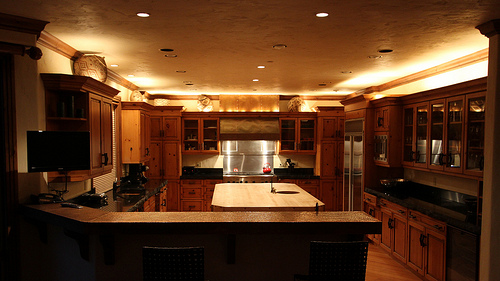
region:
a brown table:
[214, 180, 316, 208]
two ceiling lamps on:
[137, 11, 329, 19]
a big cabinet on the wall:
[50, 77, 119, 178]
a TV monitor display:
[26, 129, 91, 172]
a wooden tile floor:
[375, 252, 399, 279]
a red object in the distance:
[262, 166, 271, 174]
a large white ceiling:
[118, 9, 357, 71]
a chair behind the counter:
[147, 243, 203, 278]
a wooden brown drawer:
[406, 207, 445, 235]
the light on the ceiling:
[347, 70, 396, 94]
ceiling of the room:
[79, 0, 368, 101]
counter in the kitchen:
[68, 205, 377, 234]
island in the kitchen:
[215, 180, 320, 207]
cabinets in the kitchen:
[365, 195, 450, 267]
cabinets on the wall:
[68, 88, 110, 180]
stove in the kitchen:
[209, 140, 277, 177]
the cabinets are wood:
[150, 133, 172, 173]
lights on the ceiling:
[232, 58, 307, 90]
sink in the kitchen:
[107, 178, 139, 193]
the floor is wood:
[374, 260, 394, 277]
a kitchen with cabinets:
[146, 80, 396, 187]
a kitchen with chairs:
[112, 196, 337, 279]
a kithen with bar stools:
[128, 203, 372, 279]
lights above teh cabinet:
[64, 21, 456, 148]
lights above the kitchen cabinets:
[77, 33, 494, 132]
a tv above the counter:
[14, 98, 139, 170]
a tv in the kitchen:
[14, 100, 156, 220]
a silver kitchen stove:
[207, 136, 294, 226]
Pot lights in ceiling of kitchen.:
[246, 37, 291, 93]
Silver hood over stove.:
[219, 115, 281, 140]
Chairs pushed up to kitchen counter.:
[128, 229, 375, 280]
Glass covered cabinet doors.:
[394, 98, 477, 173]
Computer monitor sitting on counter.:
[23, 124, 100, 194]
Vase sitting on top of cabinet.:
[124, 82, 148, 113]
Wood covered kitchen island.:
[207, 174, 329, 213]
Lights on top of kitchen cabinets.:
[201, 105, 281, 119]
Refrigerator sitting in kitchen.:
[338, 114, 368, 214]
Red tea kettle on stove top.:
[257, 157, 274, 175]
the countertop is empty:
[98, 205, 395, 227]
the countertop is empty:
[115, 202, 382, 250]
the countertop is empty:
[125, 203, 419, 245]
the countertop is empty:
[108, 185, 392, 259]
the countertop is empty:
[117, 209, 384, 244]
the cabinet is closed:
[55, 71, 141, 186]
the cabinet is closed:
[74, 84, 140, 206]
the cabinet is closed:
[76, 74, 136, 193]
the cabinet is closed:
[64, 78, 137, 204]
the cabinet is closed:
[70, 70, 150, 192]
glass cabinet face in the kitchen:
[180, 117, 196, 147]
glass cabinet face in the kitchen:
[201, 117, 213, 147]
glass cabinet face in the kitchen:
[280, 117, 295, 147]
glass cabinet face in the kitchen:
[297, 116, 312, 151]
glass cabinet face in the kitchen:
[401, 107, 411, 157]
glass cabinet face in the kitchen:
[411, 106, 426, 157]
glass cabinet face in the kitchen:
[430, 103, 441, 166]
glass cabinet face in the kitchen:
[446, 100, 459, 165]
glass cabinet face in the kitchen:
[465, 95, 481, 171]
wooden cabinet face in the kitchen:
[90, 98, 105, 171]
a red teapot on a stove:
[258, 157, 273, 177]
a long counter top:
[117, 204, 380, 231]